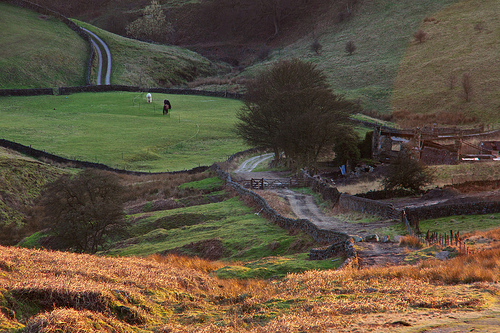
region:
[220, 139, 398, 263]
A rough country road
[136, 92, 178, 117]
animals grazing in a pasture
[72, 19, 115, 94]
A road going up a hill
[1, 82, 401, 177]
A stone fence surrounding a pasture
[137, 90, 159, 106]
A white horse grazing in a field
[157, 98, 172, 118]
a dark horse grazing in a field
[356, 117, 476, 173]
A building in ruins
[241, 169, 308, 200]
A wooden gate closing a road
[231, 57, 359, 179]
Towering trees near a turn in the road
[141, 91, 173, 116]
A dark and a light horse grazing in a field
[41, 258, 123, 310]
the grass is brown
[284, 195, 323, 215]
the road is made of dirt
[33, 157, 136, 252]
the tree is small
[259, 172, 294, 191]
the fence is wide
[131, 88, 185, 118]
the animals are grazing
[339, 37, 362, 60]
the tree is growing on the side of the mountain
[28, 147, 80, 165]
the fence is black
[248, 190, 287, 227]
the wall is short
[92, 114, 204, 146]
the field is green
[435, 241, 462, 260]
the rock is behind the grass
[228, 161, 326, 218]
fence across dirt road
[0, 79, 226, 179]
animals in a fenced field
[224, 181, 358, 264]
stone wall along a road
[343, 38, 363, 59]
short tree on a hillside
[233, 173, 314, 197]
wooden fence with gate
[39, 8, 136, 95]
road with wheel tracks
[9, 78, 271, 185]
grassy field with animals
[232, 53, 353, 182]
grove of trees beside a road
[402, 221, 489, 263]
fence posts in a row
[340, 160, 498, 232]
stone wall around field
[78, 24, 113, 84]
dirt road going down hill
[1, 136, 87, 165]
low to the ground fence made from bricks and stones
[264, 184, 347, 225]
pathway going across bumpy road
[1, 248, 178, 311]
golden grass, could be hay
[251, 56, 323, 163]
small trees in front of property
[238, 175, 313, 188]
small wooden fence dividing properties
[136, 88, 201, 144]
thin wire fence to keep animals from roaming too freely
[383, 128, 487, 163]
tall wooden fence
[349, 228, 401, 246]
rocks blocking off the road